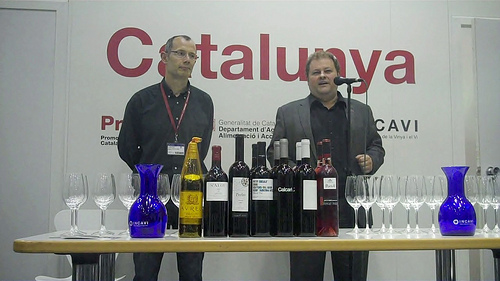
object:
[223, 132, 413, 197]
person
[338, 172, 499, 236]
glasses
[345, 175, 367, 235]
wine glass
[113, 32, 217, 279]
man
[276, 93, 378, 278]
suit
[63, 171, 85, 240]
wine glass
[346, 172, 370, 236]
glass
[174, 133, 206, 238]
wine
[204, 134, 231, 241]
wine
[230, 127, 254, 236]
wine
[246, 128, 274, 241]
wine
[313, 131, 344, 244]
wine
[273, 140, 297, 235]
bottle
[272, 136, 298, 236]
wine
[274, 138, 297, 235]
wine bottle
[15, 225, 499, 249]
table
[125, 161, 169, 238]
vase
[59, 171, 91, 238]
glass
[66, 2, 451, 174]
catalunya sign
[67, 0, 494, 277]
wall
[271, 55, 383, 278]
man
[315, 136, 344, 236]
bottle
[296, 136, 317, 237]
bottle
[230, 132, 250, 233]
bottle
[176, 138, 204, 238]
bottle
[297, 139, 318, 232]
bottle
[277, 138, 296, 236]
bottle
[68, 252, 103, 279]
leg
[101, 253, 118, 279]
leg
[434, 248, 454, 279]
leg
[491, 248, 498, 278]
leg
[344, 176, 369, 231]
wine glass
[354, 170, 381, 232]
wine glass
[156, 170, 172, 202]
wine glass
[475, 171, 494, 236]
wine glass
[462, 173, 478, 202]
wine glass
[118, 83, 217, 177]
shirt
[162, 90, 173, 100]
buttons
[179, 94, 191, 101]
buttons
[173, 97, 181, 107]
buttons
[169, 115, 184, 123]
buttons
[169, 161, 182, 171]
buttons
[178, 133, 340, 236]
wine bottles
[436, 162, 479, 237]
vase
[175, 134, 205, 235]
wine bottle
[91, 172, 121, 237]
glass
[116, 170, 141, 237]
glass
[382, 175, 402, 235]
glass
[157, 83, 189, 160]
lanyard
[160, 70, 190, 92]
man's neck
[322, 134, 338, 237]
bottle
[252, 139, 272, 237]
bottle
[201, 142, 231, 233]
wine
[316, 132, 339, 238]
wine bottle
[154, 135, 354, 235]
wine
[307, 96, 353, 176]
shirt